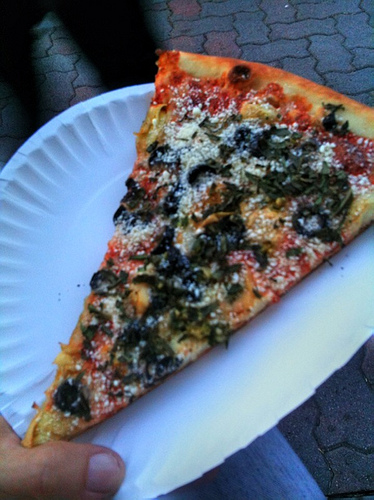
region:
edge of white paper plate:
[212, 402, 329, 454]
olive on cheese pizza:
[49, 383, 97, 422]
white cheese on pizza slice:
[85, 314, 127, 371]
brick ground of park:
[293, 419, 371, 458]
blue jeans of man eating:
[241, 448, 310, 498]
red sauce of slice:
[235, 252, 319, 312]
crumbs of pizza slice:
[47, 278, 90, 312]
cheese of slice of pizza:
[121, 282, 151, 314]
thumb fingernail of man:
[83, 431, 133, 494]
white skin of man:
[2, 422, 21, 463]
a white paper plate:
[0, 79, 371, 498]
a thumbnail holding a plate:
[80, 450, 124, 491]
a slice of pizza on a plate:
[16, 46, 372, 447]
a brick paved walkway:
[3, 3, 371, 162]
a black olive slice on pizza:
[89, 268, 127, 300]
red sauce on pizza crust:
[159, 54, 189, 95]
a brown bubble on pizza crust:
[227, 63, 253, 86]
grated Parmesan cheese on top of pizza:
[170, 125, 223, 163]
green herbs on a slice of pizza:
[261, 161, 345, 198]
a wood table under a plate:
[167, 425, 328, 498]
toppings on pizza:
[167, 182, 264, 285]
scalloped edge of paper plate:
[43, 127, 98, 194]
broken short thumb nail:
[76, 442, 135, 497]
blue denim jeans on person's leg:
[241, 453, 299, 498]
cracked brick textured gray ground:
[313, 402, 371, 479]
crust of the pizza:
[156, 41, 286, 125]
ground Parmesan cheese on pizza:
[71, 345, 125, 395]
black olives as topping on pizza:
[88, 269, 120, 291]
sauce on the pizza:
[169, 67, 239, 161]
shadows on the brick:
[16, 9, 100, 92]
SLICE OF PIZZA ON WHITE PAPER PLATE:
[62, 82, 372, 402]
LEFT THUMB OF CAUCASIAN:
[0, 428, 135, 498]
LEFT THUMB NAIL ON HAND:
[83, 455, 156, 494]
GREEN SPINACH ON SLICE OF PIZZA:
[140, 211, 191, 277]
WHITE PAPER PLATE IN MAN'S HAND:
[17, 172, 238, 477]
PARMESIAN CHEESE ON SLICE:
[169, 134, 204, 188]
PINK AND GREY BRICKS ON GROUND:
[166, 9, 361, 68]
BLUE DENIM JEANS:
[203, 442, 337, 493]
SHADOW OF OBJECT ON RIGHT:
[24, 5, 136, 73]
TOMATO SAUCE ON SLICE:
[169, 63, 367, 141]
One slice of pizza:
[31, 38, 372, 482]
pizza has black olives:
[41, 145, 357, 351]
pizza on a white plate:
[5, 69, 373, 457]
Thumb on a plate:
[1, 412, 135, 496]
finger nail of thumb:
[82, 444, 138, 498]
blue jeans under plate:
[76, 409, 361, 497]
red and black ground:
[47, 15, 370, 118]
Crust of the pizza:
[150, 50, 371, 192]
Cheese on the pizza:
[43, 131, 373, 389]